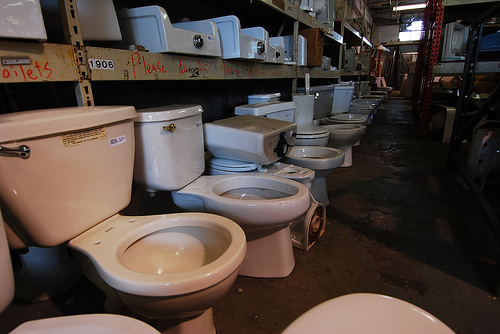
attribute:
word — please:
[122, 51, 175, 81]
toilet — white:
[8, 80, 388, 300]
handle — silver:
[0, 141, 34, 160]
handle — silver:
[158, 117, 178, 134]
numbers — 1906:
[82, 57, 126, 72]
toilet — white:
[284, 137, 345, 207]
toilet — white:
[234, 98, 334, 143]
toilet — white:
[324, 78, 369, 126]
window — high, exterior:
[391, 6, 427, 51]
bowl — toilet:
[103, 230, 236, 285]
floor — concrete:
[328, 215, 454, 283]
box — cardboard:
[300, 23, 326, 68]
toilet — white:
[160, 108, 274, 240]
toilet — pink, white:
[32, 120, 251, 330]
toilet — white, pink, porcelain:
[4, 96, 213, 287]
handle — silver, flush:
[0, 134, 31, 157]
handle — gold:
[1, 144, 32, 160]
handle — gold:
[160, 124, 177, 134]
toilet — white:
[133, 97, 310, 282]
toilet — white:
[0, 106, 247, 331]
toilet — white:
[234, 100, 344, 206]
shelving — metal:
[82, 52, 232, 95]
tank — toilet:
[197, 105, 298, 171]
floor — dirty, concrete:
[363, 79, 446, 299]